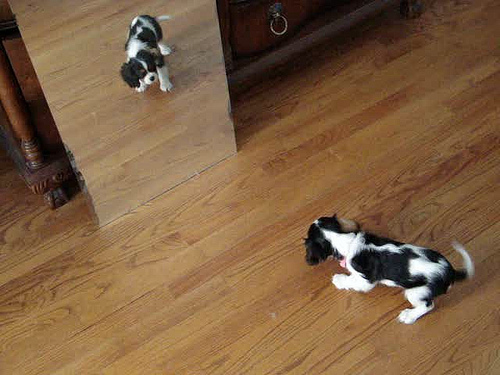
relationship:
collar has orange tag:
[332, 228, 358, 268] [337, 256, 347, 273]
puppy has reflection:
[294, 208, 483, 334] [121, 15, 176, 99]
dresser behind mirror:
[4, 1, 433, 207] [7, 0, 241, 232]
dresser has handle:
[4, 1, 433, 207] [269, 4, 289, 36]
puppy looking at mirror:
[294, 208, 483, 334] [7, 0, 241, 232]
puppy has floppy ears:
[294, 208, 483, 334] [307, 215, 356, 264]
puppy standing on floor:
[294, 208, 483, 334] [2, 15, 499, 372]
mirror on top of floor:
[7, 0, 241, 232] [2, 15, 499, 372]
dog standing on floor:
[294, 208, 483, 334] [2, 15, 499, 372]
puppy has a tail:
[294, 208, 483, 334] [445, 239, 477, 287]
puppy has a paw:
[294, 208, 483, 334] [332, 273, 352, 288]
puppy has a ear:
[294, 208, 483, 334] [307, 215, 356, 264]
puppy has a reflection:
[294, 208, 483, 334] [121, 15, 176, 99]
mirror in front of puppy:
[7, 0, 241, 232] [294, 208, 483, 334]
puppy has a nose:
[294, 208, 483, 334] [149, 73, 156, 84]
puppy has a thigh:
[294, 208, 483, 334] [405, 286, 438, 309]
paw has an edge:
[332, 273, 352, 288] [333, 285, 350, 292]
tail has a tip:
[445, 239, 477, 287] [451, 240, 465, 251]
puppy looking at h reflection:
[294, 208, 483, 334] [121, 15, 176, 99]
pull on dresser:
[269, 4, 289, 36] [4, 1, 433, 207]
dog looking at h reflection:
[294, 208, 483, 334] [121, 15, 176, 99]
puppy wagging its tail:
[294, 208, 483, 334] [445, 239, 477, 287]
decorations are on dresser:
[14, 136, 69, 193] [4, 1, 433, 207]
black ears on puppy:
[307, 215, 356, 264] [294, 208, 483, 334]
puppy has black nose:
[294, 208, 483, 334] [149, 73, 156, 84]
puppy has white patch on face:
[294, 208, 483, 334] [122, 55, 159, 90]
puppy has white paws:
[294, 208, 483, 334] [328, 276, 431, 324]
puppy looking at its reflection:
[294, 208, 483, 334] [121, 15, 176, 99]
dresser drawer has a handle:
[232, 1, 375, 57] [269, 4, 289, 36]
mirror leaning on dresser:
[7, 0, 241, 232] [4, 1, 433, 207]